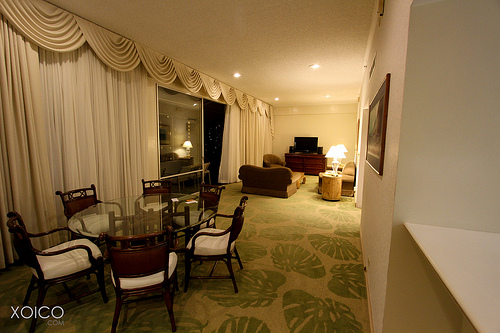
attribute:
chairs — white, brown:
[6, 200, 203, 327]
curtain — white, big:
[2, 0, 291, 210]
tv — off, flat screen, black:
[291, 135, 320, 153]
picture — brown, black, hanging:
[358, 68, 394, 182]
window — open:
[198, 94, 236, 182]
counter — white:
[401, 222, 484, 332]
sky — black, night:
[204, 102, 219, 157]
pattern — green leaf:
[258, 223, 339, 330]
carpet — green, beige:
[253, 196, 362, 331]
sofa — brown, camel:
[233, 148, 307, 197]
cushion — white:
[43, 239, 105, 281]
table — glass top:
[57, 189, 223, 242]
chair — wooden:
[92, 219, 190, 327]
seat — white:
[113, 247, 181, 288]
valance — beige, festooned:
[1, 4, 200, 89]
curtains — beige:
[16, 49, 160, 229]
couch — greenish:
[231, 160, 301, 199]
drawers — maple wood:
[276, 151, 326, 181]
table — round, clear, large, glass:
[62, 188, 223, 252]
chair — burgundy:
[83, 223, 183, 330]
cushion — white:
[30, 229, 107, 279]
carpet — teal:
[268, 279, 314, 319]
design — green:
[265, 229, 319, 277]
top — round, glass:
[100, 188, 210, 287]